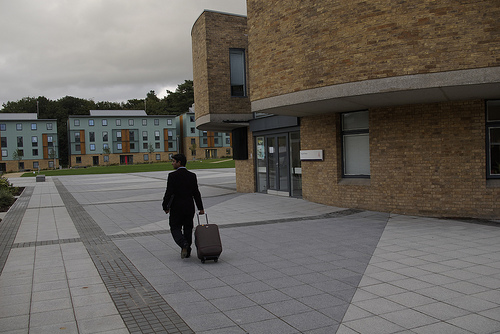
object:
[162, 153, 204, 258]
man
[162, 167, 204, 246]
suit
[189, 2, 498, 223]
building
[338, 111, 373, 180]
window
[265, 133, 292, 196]
door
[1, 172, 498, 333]
sidewalk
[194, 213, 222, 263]
luggage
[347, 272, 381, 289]
tile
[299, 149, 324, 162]
sign